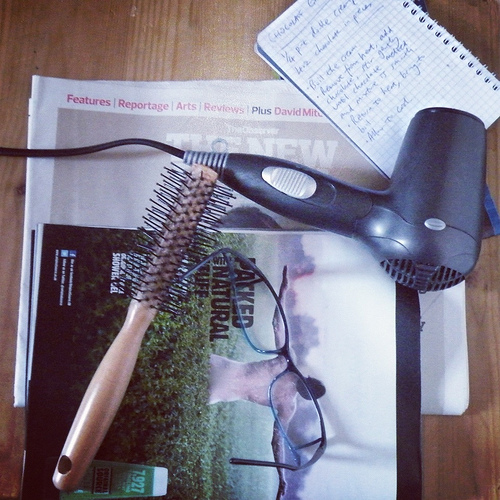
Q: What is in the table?
A: Brush.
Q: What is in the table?
A: Pad.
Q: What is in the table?
A: Paper.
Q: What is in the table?
A: Brush.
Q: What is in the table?
A: Dryer.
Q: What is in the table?
A: Book.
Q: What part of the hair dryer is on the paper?
A: Top black part.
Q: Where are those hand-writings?
A: On a small white notebook.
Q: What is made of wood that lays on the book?
A: Bottom part of brush.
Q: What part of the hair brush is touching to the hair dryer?
A: Top part of the tan brush.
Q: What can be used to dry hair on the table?
A: A black hair dryer.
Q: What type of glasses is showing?
A: Eyeglasses.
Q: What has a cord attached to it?
A: A blowdryer.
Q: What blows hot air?
A: The blowdryer.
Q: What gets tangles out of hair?
A: The hair brush.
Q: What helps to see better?
A: The glases.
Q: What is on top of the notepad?
A: The blowdryer.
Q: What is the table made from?
A: Wood.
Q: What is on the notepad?
A: Writting.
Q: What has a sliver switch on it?
A: The blowdryer.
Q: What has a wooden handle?
A: The hair brush.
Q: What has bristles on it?
A: The hair brush.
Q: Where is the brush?
A: On the magazine.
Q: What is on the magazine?
A: A person.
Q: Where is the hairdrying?
A: On the table.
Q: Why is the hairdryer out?
A: To do hair.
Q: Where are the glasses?
A: On the magazine.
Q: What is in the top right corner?
A: A notebook.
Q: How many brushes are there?
A: One.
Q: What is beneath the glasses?
A: A magazine.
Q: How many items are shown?
A: 6.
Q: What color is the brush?
A: Tan.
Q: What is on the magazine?
A: A nude man.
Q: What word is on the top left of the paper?
A: Features.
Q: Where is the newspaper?
A: On the bottom.